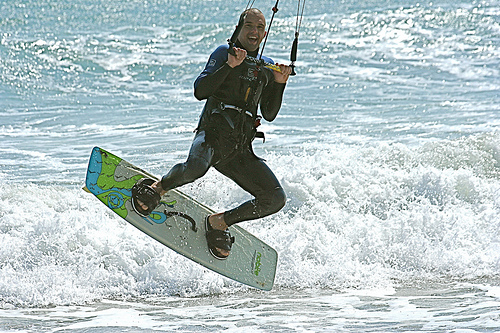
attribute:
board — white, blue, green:
[81, 139, 283, 290]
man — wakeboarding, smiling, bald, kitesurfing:
[135, 7, 293, 258]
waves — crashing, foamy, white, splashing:
[3, 138, 491, 301]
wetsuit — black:
[160, 44, 289, 224]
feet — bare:
[128, 177, 239, 260]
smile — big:
[249, 33, 256, 42]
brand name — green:
[247, 245, 266, 283]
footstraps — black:
[130, 178, 241, 259]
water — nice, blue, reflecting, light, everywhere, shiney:
[3, 4, 498, 329]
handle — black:
[167, 204, 197, 233]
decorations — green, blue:
[83, 144, 175, 235]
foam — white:
[35, 6, 490, 87]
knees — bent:
[181, 152, 289, 215]